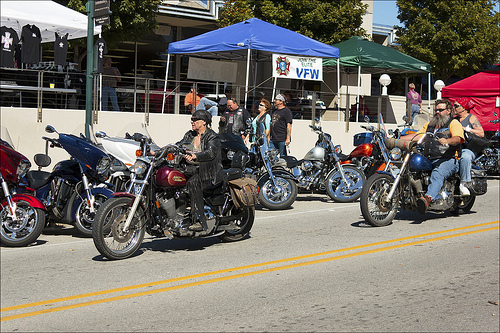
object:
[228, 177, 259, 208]
bag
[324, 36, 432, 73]
canopy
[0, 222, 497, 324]
line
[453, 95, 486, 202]
woman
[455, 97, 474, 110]
red bandanna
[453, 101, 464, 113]
head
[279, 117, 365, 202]
motorcycle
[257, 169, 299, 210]
motorcycle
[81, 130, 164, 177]
motorcycle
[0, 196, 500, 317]
sidewalk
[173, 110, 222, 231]
guy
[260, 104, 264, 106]
shades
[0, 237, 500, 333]
ground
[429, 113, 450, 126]
beard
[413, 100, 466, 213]
guy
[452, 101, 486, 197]
man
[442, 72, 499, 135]
red tent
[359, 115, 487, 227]
bike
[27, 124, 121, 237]
bike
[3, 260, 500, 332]
pavement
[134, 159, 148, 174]
light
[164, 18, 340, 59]
canopy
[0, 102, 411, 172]
sidewalk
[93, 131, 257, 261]
bike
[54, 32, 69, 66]
shirt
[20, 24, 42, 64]
shirt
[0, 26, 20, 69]
shirt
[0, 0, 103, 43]
canopy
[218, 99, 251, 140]
people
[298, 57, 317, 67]
word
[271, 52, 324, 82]
banner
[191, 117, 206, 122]
sunglasses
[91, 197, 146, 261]
wheel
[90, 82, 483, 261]
group